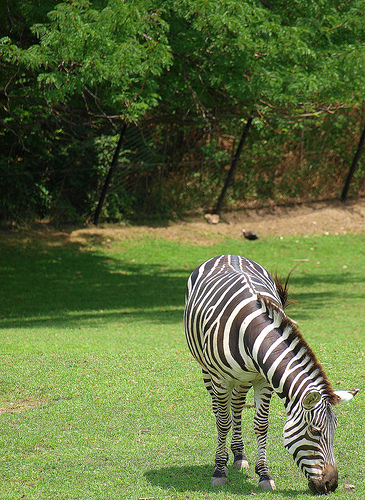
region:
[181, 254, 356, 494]
A zebra is grazing on grass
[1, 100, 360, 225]
A fence encloses the zebra's pen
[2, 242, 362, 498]
A large grassy field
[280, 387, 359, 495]
The zebra's head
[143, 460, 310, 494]
The zebra's shadow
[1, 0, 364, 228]
Trees growing behind the zebra's pen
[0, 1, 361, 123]
Tree branches extend out over the fence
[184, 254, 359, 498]
A beautiful zebra grazes on a sunny day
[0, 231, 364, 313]
Shade cast by trees growing outside the enclosure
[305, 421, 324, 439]
The zebra's eye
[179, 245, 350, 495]
zebra grazing on the grass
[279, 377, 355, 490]
zebra head eating grass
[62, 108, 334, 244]
leaning metal chain link fence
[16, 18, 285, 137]
leaning green trees with leaves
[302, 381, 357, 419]
zebra ears with a yellow tag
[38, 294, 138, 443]
green grass in a zebra enclosure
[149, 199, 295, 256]
rocks and dirt in a zebra pen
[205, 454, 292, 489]
white hooves of a zebra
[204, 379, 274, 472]
striped legs of a zebra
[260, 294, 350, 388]
striped mane of a zebra topped with black hair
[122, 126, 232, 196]
this is a FENCE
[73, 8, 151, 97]
this is a tree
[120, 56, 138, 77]
the tree has green leaves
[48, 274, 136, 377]
this is a grass area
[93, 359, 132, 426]
the grass is green in color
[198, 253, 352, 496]
this is a zebra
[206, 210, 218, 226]
this is a small rock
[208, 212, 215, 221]
the rock is brown in color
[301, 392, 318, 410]
this is the ear of the zebra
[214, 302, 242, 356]
the zebra is black and white in color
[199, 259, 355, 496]
This is a zebra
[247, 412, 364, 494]
The zebra is eating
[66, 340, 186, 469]
The grass is green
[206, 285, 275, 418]
The zebra is black and white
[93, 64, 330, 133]
There are trees in the back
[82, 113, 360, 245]
There is a fence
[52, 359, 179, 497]
The sun is shining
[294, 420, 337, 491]
The zebra's face is down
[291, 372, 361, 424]
The zebra has two ears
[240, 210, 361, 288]
There is dirt in front of the fence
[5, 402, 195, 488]
a flat grassy field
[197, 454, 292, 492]
a few animal hooves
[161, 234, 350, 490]
a black and white animal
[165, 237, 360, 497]
a zebra grazing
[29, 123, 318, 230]
a metal fence leaning in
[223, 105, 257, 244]
a black metal pole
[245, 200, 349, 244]
a patch of dirt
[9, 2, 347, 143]
a few trees outside fence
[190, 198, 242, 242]
large rock in dirt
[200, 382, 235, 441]
some black and white stripes